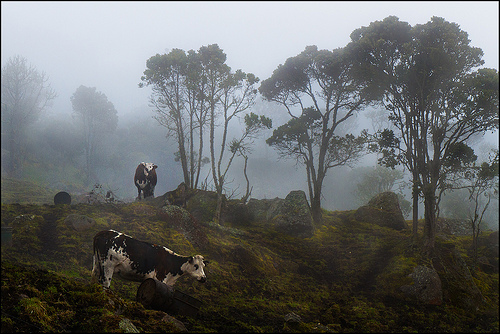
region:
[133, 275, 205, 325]
a barrel on a hillside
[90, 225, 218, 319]
a black and white cow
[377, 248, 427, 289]
moss growing on a rock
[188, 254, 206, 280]
the white face of a cow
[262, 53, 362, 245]
a tree on a hillside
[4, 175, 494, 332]
a green rocky hillside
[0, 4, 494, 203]
fog in the air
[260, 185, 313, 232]
a larg rock on a hillside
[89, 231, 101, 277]
a black and white cow tail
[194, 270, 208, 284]
a nose on a cow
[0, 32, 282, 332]
cows in a fog filled medow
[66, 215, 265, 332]
black and white cow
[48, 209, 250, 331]
cow walking down a hill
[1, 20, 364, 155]
fog filled sky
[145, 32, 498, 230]
fog around the trees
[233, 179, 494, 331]
rocks on a slope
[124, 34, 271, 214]
cow standing next to a tree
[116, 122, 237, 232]
black and white cow standing on a rock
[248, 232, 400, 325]
green grass on a hill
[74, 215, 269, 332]
fallen tree trunk in front of the cow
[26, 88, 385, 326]
cows standing in the fog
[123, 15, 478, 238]
a group of small trees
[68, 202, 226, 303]
large black and white cow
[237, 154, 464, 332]
large moss covered rocks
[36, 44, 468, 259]
foggy rocky wood area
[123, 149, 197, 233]
cow standing up on a ledge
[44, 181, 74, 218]
barrel sitting in the moss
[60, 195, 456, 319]
moss covered ground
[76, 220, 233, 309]
cow standing on uneven ground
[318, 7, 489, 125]
very leafy tree tops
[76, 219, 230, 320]
The cow is black and white.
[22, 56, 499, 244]
It is foggy outside.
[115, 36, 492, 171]
The trees are leafy on top.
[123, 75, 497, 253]
The trees are bare on the bottom.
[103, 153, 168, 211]
The cow is standing.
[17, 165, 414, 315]
They are grazing.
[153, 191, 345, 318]
The ground has large rocks.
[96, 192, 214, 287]
The grass is lush.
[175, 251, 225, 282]
The cow's face is white.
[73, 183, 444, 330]
They are walking down hill.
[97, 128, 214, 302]
cows standing in the rain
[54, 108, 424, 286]
foggy on a grassy mountainside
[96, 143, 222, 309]
black and white cows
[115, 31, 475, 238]
sparse trees on hillside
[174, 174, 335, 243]
rocks underneath trees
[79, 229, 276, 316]
cow looking down hill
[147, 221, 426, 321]
grass and dirt on hill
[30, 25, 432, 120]
thick fog above the tree line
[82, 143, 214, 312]
two cows grazing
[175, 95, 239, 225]
skinny tree trunks